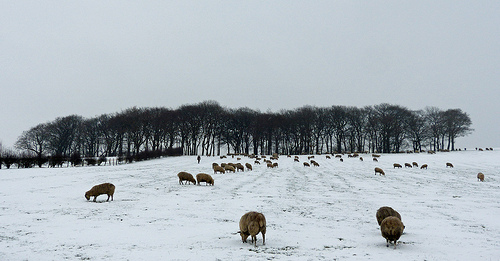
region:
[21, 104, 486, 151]
Trees in a row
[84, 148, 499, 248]
A huge group of animals outside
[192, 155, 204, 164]
A person standing outside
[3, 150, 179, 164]
Bushes near the trees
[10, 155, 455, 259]
Ground is covered in snow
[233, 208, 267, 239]
Animal is looking for something to eat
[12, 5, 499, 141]
The sky is white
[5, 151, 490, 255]
Prints that are left by the animals walking in the snow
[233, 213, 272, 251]
The animal is very fury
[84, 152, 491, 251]
All of the animals are brown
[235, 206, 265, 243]
a grey sheep grazing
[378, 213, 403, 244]
a grey sheep grazing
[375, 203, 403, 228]
a grey sheep grazing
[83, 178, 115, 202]
a grey sheep grazing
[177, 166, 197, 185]
a grey sheep grazing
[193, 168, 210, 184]
a grey sheep grazing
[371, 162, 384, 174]
a grey sheep grazing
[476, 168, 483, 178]
a grey sheep grazing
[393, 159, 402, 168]
a grey sheep grazing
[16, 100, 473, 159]
a range of bare trees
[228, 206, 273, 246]
Brown furry animal in the foreground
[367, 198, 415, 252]
Two brown furry animals in the foreground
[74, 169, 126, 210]
Brown furry animal pointed left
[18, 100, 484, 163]
Forest of trees in the background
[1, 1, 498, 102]
Cloudy gray sky above the field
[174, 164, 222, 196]
Two brown furry animals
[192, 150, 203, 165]
Small figure walking towards the animals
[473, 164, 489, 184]
Small brown furry animal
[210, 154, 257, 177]
Large group of brown furred animals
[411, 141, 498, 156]
Animals along the horizon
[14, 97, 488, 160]
THE TREES ARE IN THE DISTANCE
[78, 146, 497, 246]
THE SHEEP ARE ON THE HILL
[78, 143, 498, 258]
MANY SHEEP ARE TOGETHER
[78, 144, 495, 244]
THE SHEEP ARE BROWN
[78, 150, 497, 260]
THE SHEEP ARE WOOLY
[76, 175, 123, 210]
THIS IS A SHEEP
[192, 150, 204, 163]
THIS IS A PERSON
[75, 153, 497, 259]
THE SHEEP ARE FLUFFY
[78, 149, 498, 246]
THE SHEEP ARE FAT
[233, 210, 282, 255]
THIS SHEEP HAS HORNS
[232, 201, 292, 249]
the shep is grazing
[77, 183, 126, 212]
the sheep is grazing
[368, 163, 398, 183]
the sheep is grazing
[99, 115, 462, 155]
trees are in the background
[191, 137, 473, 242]
flock of sheep is in the snow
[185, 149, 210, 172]
the person is on the snow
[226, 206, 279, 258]
the sheep is brwon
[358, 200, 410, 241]
the heep is covered in wool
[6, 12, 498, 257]
the scene is outdoors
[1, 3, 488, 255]
the season is winter